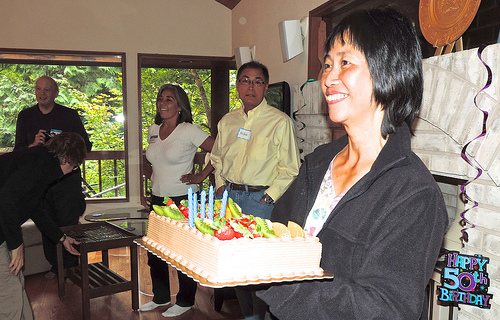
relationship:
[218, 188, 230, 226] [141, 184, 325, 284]
candle on top cake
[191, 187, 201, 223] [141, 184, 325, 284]
candle on cake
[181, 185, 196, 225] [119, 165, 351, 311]
candle on cake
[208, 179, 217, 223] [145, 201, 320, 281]
candle on cake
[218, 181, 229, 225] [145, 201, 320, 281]
candle on cake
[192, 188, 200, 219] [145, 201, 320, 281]
candle on cake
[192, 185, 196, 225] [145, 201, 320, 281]
candle on cake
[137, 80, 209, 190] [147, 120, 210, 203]
woman wearing shirt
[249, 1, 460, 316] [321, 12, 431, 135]
woman with hair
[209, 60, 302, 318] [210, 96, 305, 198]
man wearing shirt